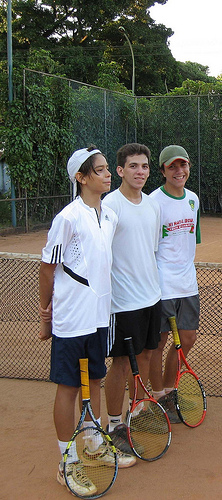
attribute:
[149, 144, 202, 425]
man — young, boy, juvenile, smiling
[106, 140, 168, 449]
man — young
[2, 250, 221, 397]
net — tennis, mesh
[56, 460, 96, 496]
shoe — athletic, white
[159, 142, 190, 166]
hat — green, backwards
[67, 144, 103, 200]
hat — white, backwards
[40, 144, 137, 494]
boy — smiling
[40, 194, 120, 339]
shirt — white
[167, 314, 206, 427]
raquet — red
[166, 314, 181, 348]
handle — yellow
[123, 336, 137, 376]
handle — black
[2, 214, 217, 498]
court — clay, tennis, sandy, dirt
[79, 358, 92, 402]
handle — yellow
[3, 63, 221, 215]
fence — tall, metal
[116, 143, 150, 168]
hair — short, brown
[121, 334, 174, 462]
racket — tennis, black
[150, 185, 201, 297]
shirt — short-sleeved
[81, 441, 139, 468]
shoe — tennis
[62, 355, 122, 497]
racket — yellow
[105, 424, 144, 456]
shoe — black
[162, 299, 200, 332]
shorts — grey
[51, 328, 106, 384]
shorts — blue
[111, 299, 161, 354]
shorts — black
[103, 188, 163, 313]
shirt — white, solid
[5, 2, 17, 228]
pole — light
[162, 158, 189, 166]
trim — orange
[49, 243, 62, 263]
stripes — black